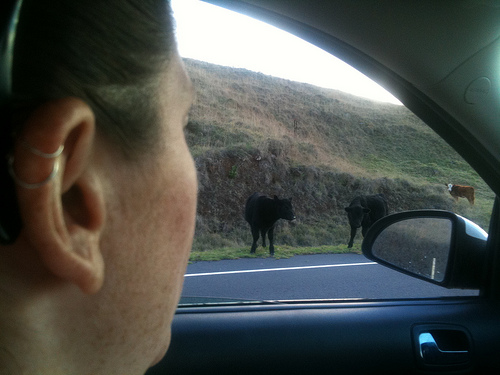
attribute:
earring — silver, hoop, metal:
[15, 132, 67, 160]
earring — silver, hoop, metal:
[6, 154, 62, 192]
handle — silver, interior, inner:
[416, 322, 472, 366]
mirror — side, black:
[347, 200, 465, 292]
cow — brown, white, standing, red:
[444, 178, 480, 211]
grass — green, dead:
[178, 55, 498, 264]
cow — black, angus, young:
[338, 188, 386, 257]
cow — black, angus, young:
[239, 187, 299, 261]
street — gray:
[172, 243, 481, 305]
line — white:
[189, 257, 378, 279]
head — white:
[443, 181, 455, 195]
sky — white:
[167, 2, 406, 110]